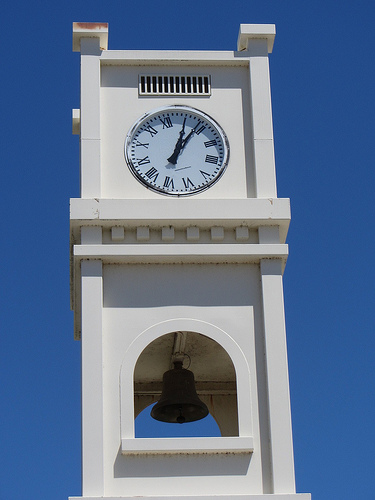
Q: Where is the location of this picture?
A: Bell tower.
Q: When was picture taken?
A: 1:09.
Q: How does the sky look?
A: Beautiful blue.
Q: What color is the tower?
A: White.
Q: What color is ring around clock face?
A: Silver.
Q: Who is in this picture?
A: No one.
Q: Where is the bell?
A: Below clock.